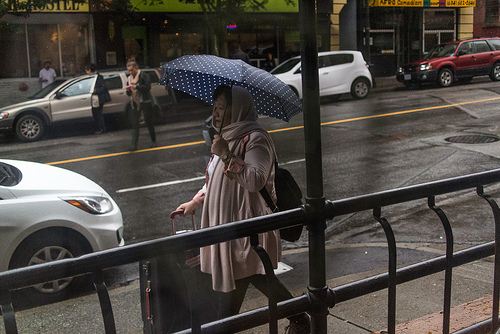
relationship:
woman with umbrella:
[185, 100, 268, 222] [161, 53, 305, 126]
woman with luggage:
[185, 100, 268, 222] [135, 207, 223, 330]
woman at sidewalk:
[185, 100, 268, 222] [59, 220, 318, 326]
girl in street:
[119, 53, 165, 143] [67, 78, 364, 173]